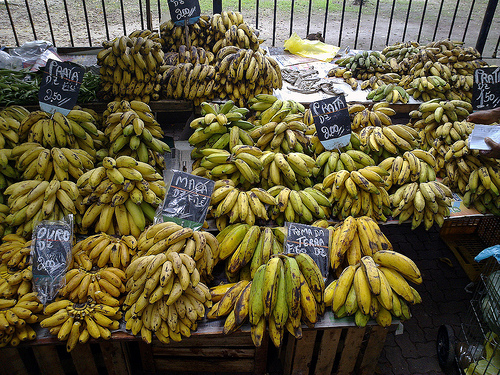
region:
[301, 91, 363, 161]
a black sign with white writting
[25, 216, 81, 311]
plastic over a black sign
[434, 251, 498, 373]
a shopping cart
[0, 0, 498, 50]
a metal gate behind the bananas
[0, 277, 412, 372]
bananas on wooden crates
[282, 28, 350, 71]
plastic yellow bag next to the gate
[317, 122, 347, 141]
numbers on a black sign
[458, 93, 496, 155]
a hand holding a piece of paper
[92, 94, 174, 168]
a bunch of green and yellow bananas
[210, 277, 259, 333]
over ripe bananas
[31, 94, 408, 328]
these are yellow bananas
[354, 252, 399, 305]
this is a yellow banana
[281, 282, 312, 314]
these are bruises banans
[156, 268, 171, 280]
this is a banana bruise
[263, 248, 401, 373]
this is a crate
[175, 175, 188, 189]
this is the letter M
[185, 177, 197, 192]
the white letter A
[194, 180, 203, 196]
the white letter C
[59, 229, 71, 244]
the white letter O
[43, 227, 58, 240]
the white letter U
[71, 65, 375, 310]
selling plenty yellow bananas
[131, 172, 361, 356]
selling plenty yellow bananas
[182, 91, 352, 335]
selling plenty yellow bananas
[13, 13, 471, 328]
a large lot of bananas for sale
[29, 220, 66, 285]
a black sign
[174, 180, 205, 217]
white writing on the sign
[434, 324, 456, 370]
a the black rubber wheel on a cart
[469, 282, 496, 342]
metal prongs in a cart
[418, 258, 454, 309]
bricks in the sidewalk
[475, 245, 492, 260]
a blue plastic bag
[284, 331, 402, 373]
a wooden crate under the bananas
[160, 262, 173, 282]
brown spots on the banana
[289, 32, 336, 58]
yellow plastic bags stacked near the fence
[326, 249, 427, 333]
a yellow bunch of bananas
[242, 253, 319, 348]
a yellow bunch of bananas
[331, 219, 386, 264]
a yellow bunch of bananas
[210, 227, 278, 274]
a yellow bunch of bananas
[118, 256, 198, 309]
a yellow bunch of bananas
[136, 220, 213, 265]
a yellow bunch of bananas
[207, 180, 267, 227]
a yellow bunch of bananas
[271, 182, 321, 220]
a yellow bunch of bananas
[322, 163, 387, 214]
a yellow bunch of bananas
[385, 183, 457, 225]
a yellow bunch of bananas